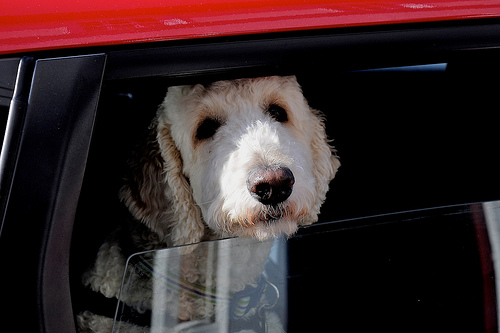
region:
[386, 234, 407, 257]
part of a window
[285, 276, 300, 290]
side of a window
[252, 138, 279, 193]
nose of a dog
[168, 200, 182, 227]
part of a belt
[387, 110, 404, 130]
part of a darkness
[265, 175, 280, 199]
nose of a dog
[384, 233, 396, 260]
edge of a window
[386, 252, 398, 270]
part of a window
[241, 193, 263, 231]
mouth of a dog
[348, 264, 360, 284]
side of a window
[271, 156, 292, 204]
nose of a dog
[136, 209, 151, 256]
part of a belt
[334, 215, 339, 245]
edge of a window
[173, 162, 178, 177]
edge of an ear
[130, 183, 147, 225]
part of a cloth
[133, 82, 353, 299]
a shaggy dog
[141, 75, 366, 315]
a dog sticking its head out the windo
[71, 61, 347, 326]
a dog with its head out a car window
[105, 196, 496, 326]
a car window rolled halfway down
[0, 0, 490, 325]
a dog in a red car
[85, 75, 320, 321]
a dog wearing a collar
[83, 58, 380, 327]
a dog sitting inside a car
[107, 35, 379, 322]
a dog looking out a window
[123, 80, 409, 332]
a white dog with its head outside a window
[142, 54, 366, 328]
a dog sitting inside a red vehicle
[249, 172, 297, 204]
black nose of dog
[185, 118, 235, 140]
black eye of dog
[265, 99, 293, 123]
black eye of dog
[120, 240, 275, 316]
collar around neck of dog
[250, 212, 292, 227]
mouth of dog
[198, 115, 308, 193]
white snout of dog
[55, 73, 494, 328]
dog in car window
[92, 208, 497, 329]
window of car rolled down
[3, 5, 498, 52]
roof of car is red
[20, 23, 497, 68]
black part of car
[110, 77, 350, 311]
The dog is white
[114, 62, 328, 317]
The dog is looking out the window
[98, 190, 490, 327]
The window is halfway down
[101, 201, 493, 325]
The window is clear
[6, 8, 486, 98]
The vehicle is red and black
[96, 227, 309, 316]
The dog is wearing a collar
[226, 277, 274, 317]
The collar has a black strap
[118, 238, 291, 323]
The collar is striped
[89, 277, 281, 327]
Black harness around dog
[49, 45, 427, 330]
The dog is inside a vehicle